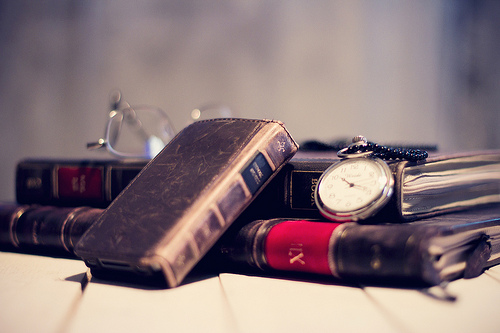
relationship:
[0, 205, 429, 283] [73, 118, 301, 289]
edge of bible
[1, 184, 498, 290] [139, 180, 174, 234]
antique book made of leather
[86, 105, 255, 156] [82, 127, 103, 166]
eye glass with frames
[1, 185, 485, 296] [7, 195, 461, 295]
antique book with roun spine